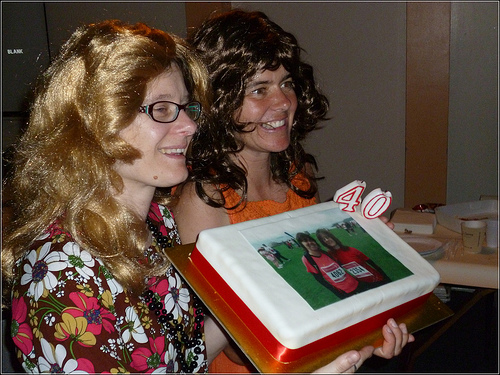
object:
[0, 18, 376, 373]
woman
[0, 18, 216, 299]
wig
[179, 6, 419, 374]
woman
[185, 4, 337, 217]
wig